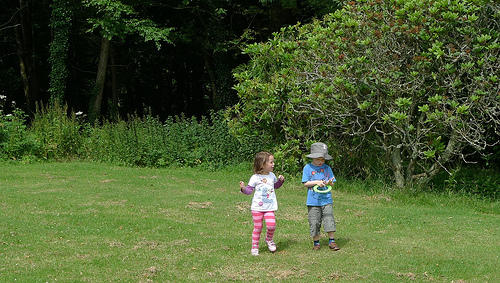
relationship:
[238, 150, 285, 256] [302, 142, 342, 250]
girl next to boy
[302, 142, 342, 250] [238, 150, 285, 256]
boy next to girl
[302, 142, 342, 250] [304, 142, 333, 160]
boy wearing hat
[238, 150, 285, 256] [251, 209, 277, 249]
girl wearing tights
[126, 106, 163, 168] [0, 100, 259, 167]
plants organized in a row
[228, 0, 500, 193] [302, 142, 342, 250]
tree behind boy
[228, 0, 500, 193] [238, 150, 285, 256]
tree behind girl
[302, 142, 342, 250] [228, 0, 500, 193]
boy in front of tree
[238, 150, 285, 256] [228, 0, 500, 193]
girl in front of tree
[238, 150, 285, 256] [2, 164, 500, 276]
girl walking on grass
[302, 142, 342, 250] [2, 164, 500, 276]
boy walking on grass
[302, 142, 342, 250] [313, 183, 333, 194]
boy holding toy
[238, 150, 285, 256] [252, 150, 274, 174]
girl has hair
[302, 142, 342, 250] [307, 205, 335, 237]
boy wearing shorts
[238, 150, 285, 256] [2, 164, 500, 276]
girl on top of grass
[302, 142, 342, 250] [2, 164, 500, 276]
boy on top of grass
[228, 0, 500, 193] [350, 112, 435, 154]
tree has branches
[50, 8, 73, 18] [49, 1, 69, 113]
vines cover tree trunk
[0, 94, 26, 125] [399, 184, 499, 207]
queen annes lace across from tall grass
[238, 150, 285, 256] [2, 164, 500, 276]
girl playing on grass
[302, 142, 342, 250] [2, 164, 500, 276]
boy playing on grass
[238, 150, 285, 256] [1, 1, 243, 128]
girl near forest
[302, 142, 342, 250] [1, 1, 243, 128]
boy near forest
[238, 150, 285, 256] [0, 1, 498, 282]
girl standing in backyard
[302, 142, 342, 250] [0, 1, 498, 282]
boy standing in backyard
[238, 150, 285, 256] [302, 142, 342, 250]
girl looking at boy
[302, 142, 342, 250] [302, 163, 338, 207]
boy wearing t-shirt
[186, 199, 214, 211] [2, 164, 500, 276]
pile of grass on top of grass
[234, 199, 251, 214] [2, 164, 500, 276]
pile of grass on top of grass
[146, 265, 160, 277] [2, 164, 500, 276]
pile of grass on top of grass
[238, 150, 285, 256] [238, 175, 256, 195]
girl has arms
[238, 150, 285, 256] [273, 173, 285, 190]
girl has arms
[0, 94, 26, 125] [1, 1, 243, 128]
queen annes lace in front of forest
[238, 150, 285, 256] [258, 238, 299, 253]
girl has shadow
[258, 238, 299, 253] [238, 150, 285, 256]
shadow beneath girl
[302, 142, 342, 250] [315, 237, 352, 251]
boy has shadow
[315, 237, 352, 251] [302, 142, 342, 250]
shadow beneath boy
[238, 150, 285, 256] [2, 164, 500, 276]
girl walking through grass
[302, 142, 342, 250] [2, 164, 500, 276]
boy walking through grass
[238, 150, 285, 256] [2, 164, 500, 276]
girl in on top of grass